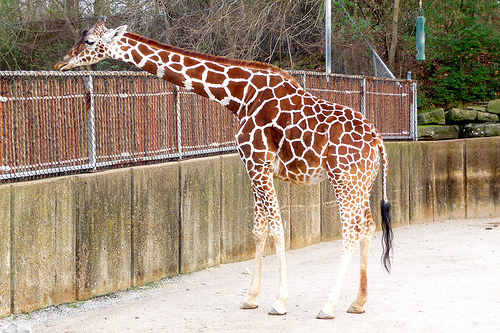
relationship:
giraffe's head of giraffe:
[54, 16, 128, 71] [51, 56, 464, 290]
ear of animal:
[105, 22, 129, 43] [44, 11, 395, 322]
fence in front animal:
[0, 70, 419, 180] [44, 11, 395, 322]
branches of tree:
[248, 56, 290, 69] [19, 106, 57, 137]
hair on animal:
[125, 30, 297, 89] [54, 16, 393, 319]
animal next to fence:
[54, 16, 393, 319] [0, 66, 417, 183]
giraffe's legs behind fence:
[240, 164, 376, 319] [0, 66, 417, 183]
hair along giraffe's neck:
[123, 31, 295, 82] [121, 35, 243, 110]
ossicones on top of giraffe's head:
[93, 14, 110, 27] [55, 23, 119, 71]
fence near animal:
[0, 66, 417, 183] [54, 16, 393, 319]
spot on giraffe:
[58, 17, 427, 305] [75, 23, 398, 322]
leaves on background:
[406, 0, 498, 103] [328, 1, 484, 121]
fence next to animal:
[0, 70, 419, 180] [54, 16, 393, 319]